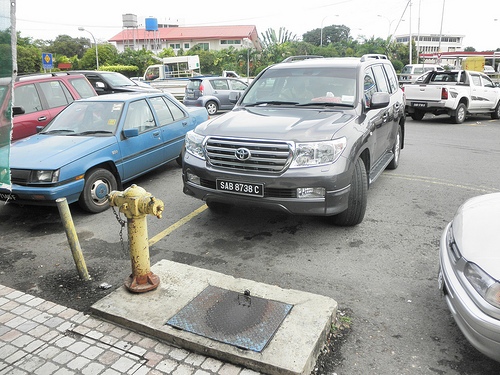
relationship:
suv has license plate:
[183, 54, 406, 227] [214, 177, 265, 197]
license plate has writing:
[214, 177, 265, 197] [219, 181, 263, 193]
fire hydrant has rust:
[107, 183, 166, 293] [125, 217, 140, 231]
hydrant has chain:
[107, 183, 166, 293] [111, 208, 135, 256]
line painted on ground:
[148, 201, 209, 248] [0, 113, 499, 373]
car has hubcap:
[2, 90, 213, 213] [90, 179, 114, 205]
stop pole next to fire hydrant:
[54, 197, 93, 280] [107, 183, 166, 293]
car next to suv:
[2, 90, 213, 213] [183, 54, 406, 227]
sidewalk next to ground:
[0, 282, 266, 374] [0, 113, 499, 373]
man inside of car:
[284, 79, 313, 100] [183, 54, 406, 227]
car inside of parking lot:
[2, 90, 213, 213] [0, 113, 499, 373]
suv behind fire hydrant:
[183, 54, 406, 227] [107, 183, 166, 293]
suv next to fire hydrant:
[183, 54, 406, 227] [107, 183, 166, 293]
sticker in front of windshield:
[340, 94, 357, 102] [242, 66, 358, 107]